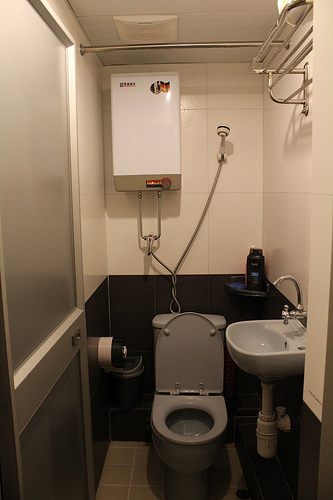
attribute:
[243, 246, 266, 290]
shampoo bottle — black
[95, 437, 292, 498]
floor — brown, tile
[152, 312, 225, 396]
seat lid — uplifted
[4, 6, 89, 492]
door — bathroom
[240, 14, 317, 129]
shelving — metal, empty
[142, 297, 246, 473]
toilet — gray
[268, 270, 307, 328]
faucet — silver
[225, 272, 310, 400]
sink — bathroom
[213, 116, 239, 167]
head — shower, white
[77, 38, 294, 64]
rod — silver, curtain, shower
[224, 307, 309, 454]
sink — white, ceramic, hanging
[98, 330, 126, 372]
towel — paper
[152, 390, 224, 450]
seat — gray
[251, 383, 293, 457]
pipes — sink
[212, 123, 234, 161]
head — shower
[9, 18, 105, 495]
door — white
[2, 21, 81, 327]
glass — frosty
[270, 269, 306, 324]
head — silver, rounded, faucet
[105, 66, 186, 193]
box — white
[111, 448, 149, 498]
floor — gray, tile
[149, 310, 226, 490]
toilet — porcelain, grey, gray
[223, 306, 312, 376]
sink — bathroom, porcelain, white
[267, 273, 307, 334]
faucet — chrome, bathroom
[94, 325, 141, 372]
paper — toilet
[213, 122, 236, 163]
head — shower, mounted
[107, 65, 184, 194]
tank — large, white, small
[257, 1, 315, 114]
rack — overhead, towel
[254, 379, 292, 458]
pvc pipe — white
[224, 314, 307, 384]
sink — white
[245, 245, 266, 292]
container — black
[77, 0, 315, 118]
rods — silver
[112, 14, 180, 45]
vent — white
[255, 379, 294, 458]
pipe — white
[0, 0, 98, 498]
door — gray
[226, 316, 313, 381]
sink — white, wall mounted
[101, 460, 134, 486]
tile — beige